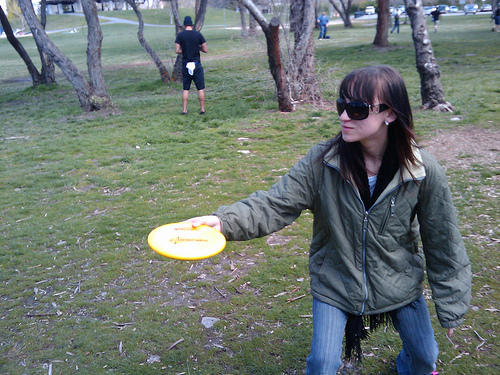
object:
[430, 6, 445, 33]
person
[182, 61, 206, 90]
shorts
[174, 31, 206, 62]
dark clothing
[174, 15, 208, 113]
arms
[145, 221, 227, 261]
purple pod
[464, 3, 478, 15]
car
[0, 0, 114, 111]
trunk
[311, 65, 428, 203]
hair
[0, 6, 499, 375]
ground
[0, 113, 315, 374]
grass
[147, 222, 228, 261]
frisbee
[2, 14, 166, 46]
paved paths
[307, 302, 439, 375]
jeans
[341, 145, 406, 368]
scarf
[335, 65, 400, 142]
head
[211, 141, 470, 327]
green jacket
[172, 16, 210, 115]
backside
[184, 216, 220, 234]
hand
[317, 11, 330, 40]
man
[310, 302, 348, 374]
leg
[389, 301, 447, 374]
leg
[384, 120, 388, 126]
earring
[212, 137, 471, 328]
coat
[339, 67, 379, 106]
bangs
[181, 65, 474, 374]
people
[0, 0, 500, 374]
park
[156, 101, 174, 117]
bent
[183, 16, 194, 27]
beanie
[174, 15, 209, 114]
he